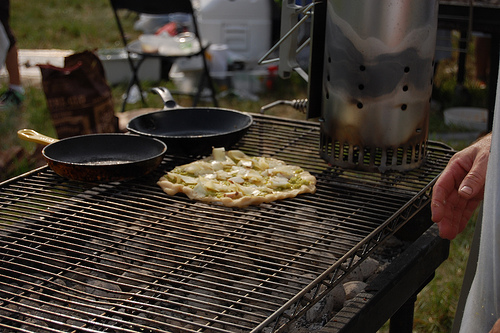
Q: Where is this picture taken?
A: It looks like its was taken in the back yard.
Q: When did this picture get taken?
A: It was taken in the day time.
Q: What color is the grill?
A: The grill is black.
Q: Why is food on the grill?
A: Because the man is cooking.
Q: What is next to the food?
A: Two skillets are next to the food.